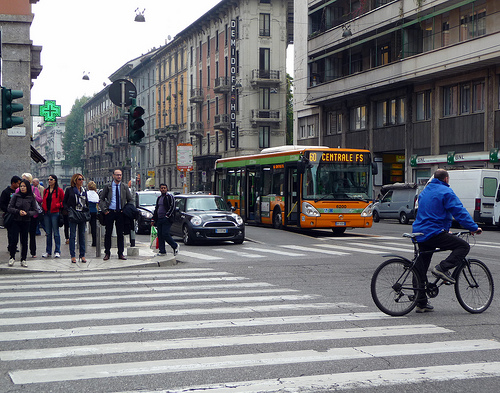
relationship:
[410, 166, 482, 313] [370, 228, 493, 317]
man riding a bicycle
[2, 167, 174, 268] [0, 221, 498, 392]
people are crossing street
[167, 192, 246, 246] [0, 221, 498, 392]
car stopped on street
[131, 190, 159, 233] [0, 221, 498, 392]
car stopped on street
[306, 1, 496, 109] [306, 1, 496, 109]
balcony on balcony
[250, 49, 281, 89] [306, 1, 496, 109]
balcony on balcony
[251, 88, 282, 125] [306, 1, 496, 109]
balcony on balcony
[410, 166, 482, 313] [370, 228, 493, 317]
man riding bicycle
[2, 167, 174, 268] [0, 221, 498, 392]
people waiting to cross street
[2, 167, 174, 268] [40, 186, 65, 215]
people wearing a jacket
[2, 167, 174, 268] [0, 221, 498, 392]
people walking on street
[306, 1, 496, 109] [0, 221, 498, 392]
balcony beside of street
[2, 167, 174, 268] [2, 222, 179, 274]
people standing on sidewalk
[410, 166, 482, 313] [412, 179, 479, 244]
man wearing jacket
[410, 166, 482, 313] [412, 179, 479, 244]
man wearing a jacket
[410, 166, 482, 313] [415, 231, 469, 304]
man wearing pants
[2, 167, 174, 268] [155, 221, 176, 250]
people wearing pants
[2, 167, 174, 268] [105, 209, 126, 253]
people wearing pants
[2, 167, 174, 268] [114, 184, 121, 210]
people wearing a tie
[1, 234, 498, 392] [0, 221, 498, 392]
lines are on street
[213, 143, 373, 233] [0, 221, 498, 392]
bus driving on street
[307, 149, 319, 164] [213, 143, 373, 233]
number on bus